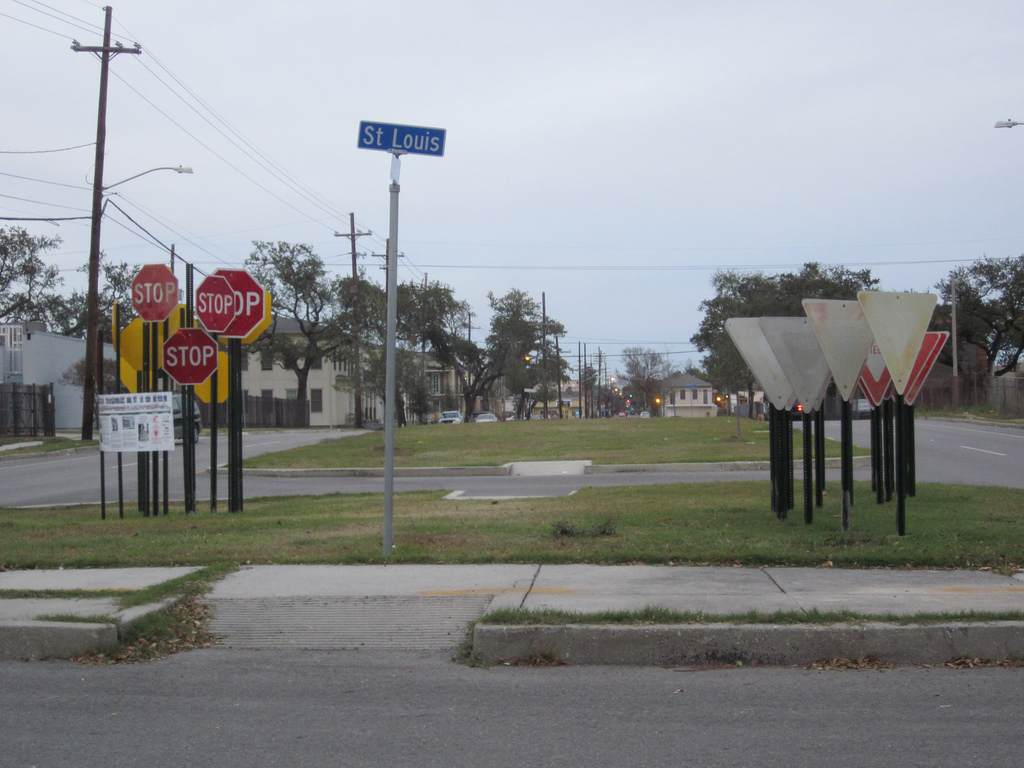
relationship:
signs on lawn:
[717, 283, 937, 544] [19, 493, 1021, 593]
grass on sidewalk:
[480, 601, 1022, 624] [0, 566, 1021, 611]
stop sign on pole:
[135, 258, 184, 320] [143, 327, 172, 511]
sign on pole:
[356, 114, 449, 160] [376, 149, 402, 557]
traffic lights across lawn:
[642, 383, 729, 414] [378, 383, 824, 482]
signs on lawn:
[120, 263, 273, 402] [5, 485, 1023, 591]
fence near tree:
[233, 385, 316, 427] [219, 224, 362, 446]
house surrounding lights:
[641, 369, 749, 442] [532, 352, 716, 416]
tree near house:
[338, 284, 383, 431] [227, 312, 366, 421]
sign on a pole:
[378, 161, 409, 298] [369, 181, 415, 561]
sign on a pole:
[192, 275, 235, 336] [95, 256, 283, 511]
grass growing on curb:
[477, 603, 1022, 625] [465, 618, 1022, 670]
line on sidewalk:
[414, 577, 591, 600] [0, 557, 1022, 621]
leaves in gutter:
[117, 615, 201, 663] [70, 592, 222, 673]